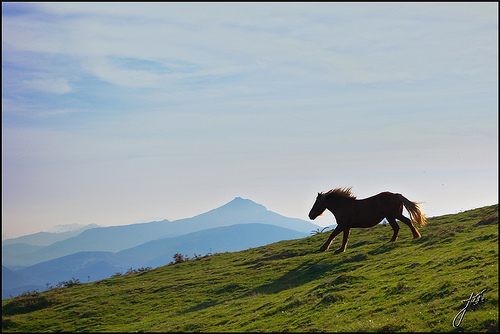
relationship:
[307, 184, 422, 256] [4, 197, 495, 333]
horse in field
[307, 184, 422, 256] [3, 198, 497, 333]
horse on hill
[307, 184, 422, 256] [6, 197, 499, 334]
horse on grass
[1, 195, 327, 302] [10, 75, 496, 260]
mountains in background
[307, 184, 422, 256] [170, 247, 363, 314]
horse has shadow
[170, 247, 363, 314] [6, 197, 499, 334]
shadow on grass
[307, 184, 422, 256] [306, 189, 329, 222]
horse has head